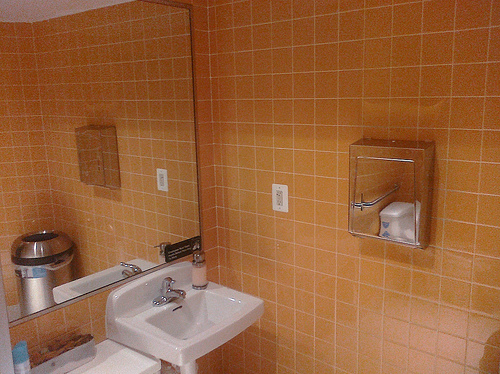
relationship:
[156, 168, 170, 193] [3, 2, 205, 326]
outlet reflecting in mirror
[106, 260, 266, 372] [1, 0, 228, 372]
sink attached wall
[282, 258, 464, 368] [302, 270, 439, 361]
tile has grout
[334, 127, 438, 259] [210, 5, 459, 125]
container on wall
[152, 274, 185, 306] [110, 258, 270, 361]
faucet on sink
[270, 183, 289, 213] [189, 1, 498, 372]
outlet on wall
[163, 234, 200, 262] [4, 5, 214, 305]
black sign on mirror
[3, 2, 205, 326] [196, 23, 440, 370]
mirror on wall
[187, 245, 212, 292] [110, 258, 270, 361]
soap on sink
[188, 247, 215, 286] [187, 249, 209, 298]
container of soap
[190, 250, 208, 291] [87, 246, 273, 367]
soap on sink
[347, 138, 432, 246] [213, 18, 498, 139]
dispenser on wall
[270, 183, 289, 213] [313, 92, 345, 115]
outlet in wall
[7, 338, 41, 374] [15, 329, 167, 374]
item on toilet